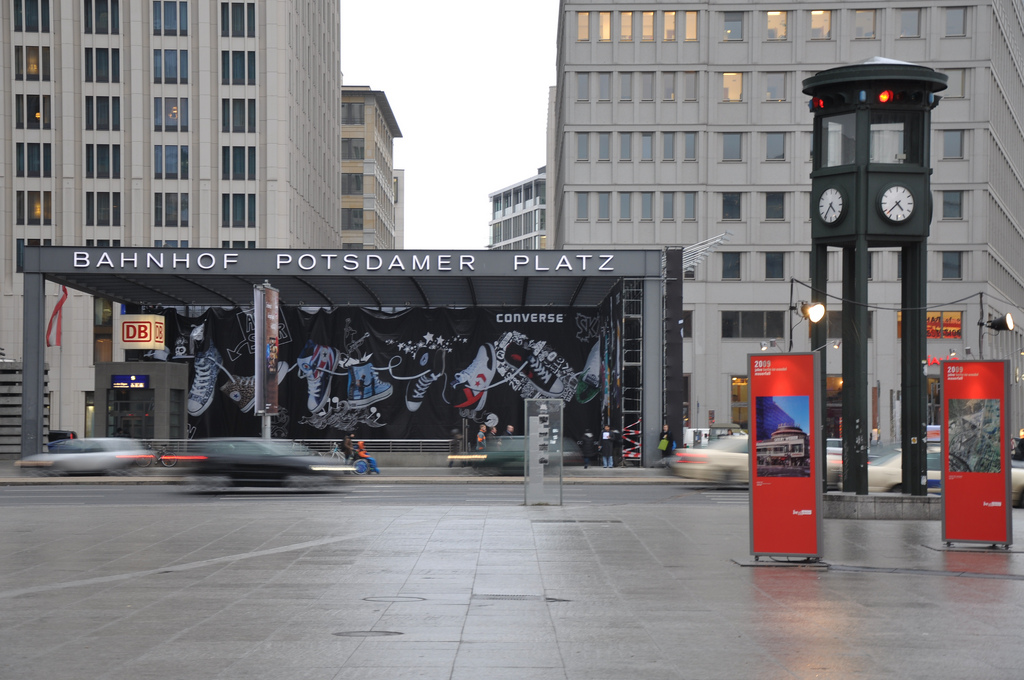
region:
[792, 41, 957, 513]
a tall steel structure with a several clocks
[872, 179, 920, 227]
a white wall clock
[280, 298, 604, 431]
a sneakers brand tarpauline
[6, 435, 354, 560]
vehicles passing on a road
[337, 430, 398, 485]
a person in a wheel chair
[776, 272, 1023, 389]
a pair of spot lights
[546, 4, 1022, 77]
a floor on an office building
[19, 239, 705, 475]
a steel structure that looks like a stage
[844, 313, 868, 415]
The pillar of the clock tower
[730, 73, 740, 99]
Interior light shining through a window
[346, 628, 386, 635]
A manhole in the near foreground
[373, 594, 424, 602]
A manhole situated on the far side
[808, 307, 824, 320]
A flood light shining below the clock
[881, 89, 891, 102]
A red light on the clock tower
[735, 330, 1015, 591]
Board is red color.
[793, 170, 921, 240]
Clock is black and white color.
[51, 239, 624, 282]
Letters are white color.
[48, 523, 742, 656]
sidewalk is grey color.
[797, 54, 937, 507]
two clocks on a black tower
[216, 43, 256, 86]
cabinet is wood and white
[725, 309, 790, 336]
cabinet is wood and white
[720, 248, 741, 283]
cabinet is wood and white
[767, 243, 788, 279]
cabinet is wood and white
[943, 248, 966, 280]
cabinet is wood and white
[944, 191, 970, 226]
cabinet is wood and white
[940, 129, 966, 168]
cabinet is wood and white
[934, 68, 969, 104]
cabinet is wood and white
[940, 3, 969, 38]
cabinet is wood and white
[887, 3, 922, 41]
cabinet is wood and white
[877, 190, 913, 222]
The clock positioned forward on the monument.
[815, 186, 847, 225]
The clock positioned towards the left on the monument.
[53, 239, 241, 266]
The word BAHNHOF on the top of the structure.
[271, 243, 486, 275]
The word POTSDAMER on the structure.